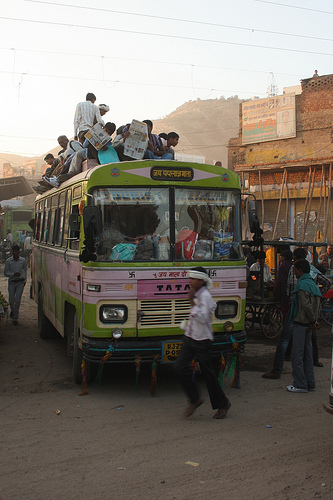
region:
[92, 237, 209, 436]
man is wearing white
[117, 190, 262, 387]
man is wearing white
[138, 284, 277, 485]
man is wearing white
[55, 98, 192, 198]
group of people on bus stop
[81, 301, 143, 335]
bus is lime green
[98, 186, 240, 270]
front windshield on green bus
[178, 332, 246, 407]
person running in dark pants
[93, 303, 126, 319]
headlamp of big green bus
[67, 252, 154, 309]
pink stripe on green bus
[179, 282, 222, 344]
person running with white shirt on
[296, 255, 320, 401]
man wearing gray pants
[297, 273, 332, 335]
man wearing gray sweater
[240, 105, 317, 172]
sign on wood and brick building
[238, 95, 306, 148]
sign on top of building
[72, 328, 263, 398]
tassles hanging from front bumper of bus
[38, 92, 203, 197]
group of people on top of bus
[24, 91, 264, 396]
bus packed full of people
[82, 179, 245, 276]
front window of bus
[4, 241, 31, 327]
man walking beside bus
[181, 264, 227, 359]
boy wearing white shirt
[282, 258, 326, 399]
man standing with arms behind him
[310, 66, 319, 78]
person on roof top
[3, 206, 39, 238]
green bus in background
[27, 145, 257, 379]
a large green bus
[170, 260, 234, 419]
a man walking in street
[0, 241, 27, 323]
a man walking in street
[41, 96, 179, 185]
people sitting on top of bus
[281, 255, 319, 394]
man standing in street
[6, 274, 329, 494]
an unpaved dirt road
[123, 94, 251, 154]
a barren hill in distance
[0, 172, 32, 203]
a white canopy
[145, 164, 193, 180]
bus destination sign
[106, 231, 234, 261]
luggage piled in window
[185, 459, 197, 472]
yellow mark is spotted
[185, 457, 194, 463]
yellow mark is spotted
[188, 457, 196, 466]
yellow mark is spotted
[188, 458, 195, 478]
yellow mark is spotted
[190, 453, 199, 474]
yellow mark is spotted